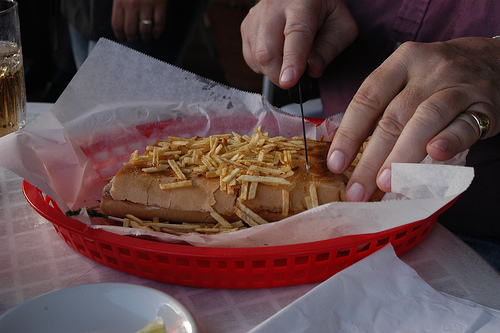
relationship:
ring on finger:
[470, 110, 492, 141] [426, 104, 500, 161]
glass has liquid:
[0, 3, 28, 140] [1, 44, 26, 133]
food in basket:
[98, 131, 396, 227] [22, 111, 469, 287]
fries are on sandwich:
[134, 134, 340, 189] [98, 131, 396, 227]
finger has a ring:
[426, 104, 500, 161] [470, 110, 492, 141]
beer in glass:
[1, 44, 26, 133] [0, 3, 28, 140]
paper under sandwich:
[1, 37, 319, 208] [98, 131, 396, 227]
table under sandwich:
[1, 102, 500, 332] [98, 131, 396, 227]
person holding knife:
[240, 1, 500, 202] [296, 81, 313, 169]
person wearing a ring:
[240, 1, 500, 202] [470, 110, 492, 141]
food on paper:
[98, 131, 396, 227] [1, 37, 319, 208]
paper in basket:
[1, 37, 319, 208] [22, 111, 469, 287]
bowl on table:
[4, 282, 201, 331] [1, 102, 500, 332]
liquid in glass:
[1, 44, 26, 133] [0, 3, 28, 140]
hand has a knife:
[241, 1, 357, 90] [296, 81, 313, 169]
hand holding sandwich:
[327, 38, 499, 201] [98, 131, 396, 227]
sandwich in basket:
[98, 131, 396, 227] [22, 111, 469, 287]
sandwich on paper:
[98, 131, 396, 227] [1, 37, 319, 208]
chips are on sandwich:
[134, 134, 340, 189] [98, 131, 396, 227]